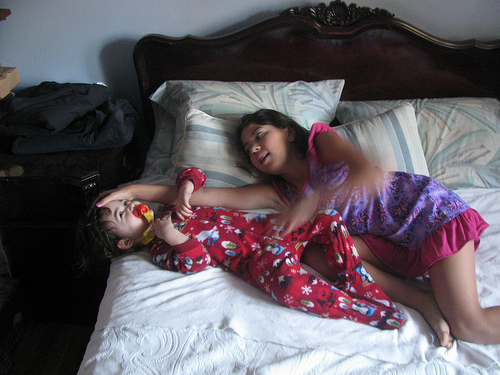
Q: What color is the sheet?
A: White.